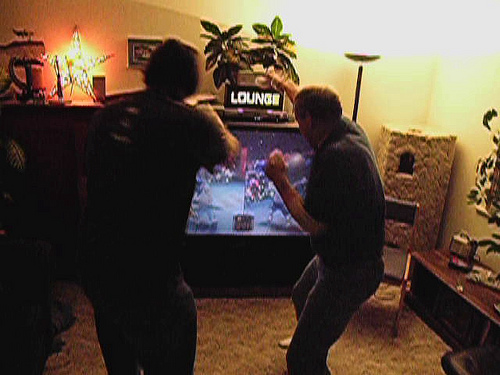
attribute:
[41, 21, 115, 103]
star — illuminated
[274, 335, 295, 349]
sock — white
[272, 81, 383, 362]
man — some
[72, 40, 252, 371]
person — wearing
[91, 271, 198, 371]
pants — dark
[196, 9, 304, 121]
potted plant — broad leafed